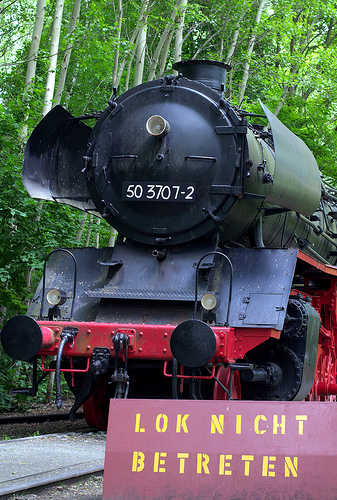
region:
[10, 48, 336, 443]
Black and red train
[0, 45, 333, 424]
Train on the tracks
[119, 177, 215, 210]
50 3707-2 on the front of the train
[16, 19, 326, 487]
Photo taken during the day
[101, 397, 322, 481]
Yellow lettering on a red sign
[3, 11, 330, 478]
No people shown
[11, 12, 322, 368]
Trees behind the train.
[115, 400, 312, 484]
"Lok Nicht Betreten" on a sign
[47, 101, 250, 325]
Three lights on the train.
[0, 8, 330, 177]
Green leaves on the trees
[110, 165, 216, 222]
numbers are on train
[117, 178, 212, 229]
the numbers are white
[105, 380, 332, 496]
the sign is red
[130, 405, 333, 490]
letters are on the sign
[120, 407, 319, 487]
the letters are yellow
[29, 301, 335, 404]
base of train is red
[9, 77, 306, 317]
the train is black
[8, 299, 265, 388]
round objects on front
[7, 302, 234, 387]
round objects are black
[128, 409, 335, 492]
words in a foreign language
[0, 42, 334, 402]
an old train engine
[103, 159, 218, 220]
train has a number 50 3707-2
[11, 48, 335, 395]
train engine is green, black and red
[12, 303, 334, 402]
lower part of the train is red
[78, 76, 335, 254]
upper part of the train is green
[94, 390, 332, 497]
a purple sign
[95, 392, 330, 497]
a rectangular sign is purple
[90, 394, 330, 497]
sign has yellow letters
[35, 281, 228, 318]
headlights are small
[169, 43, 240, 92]
tube on top is black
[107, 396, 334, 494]
red do not enter sign in German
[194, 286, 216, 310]
train engine left headlight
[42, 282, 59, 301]
train engine right headlight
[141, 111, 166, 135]
train engine top headlight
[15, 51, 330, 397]
a steam train engine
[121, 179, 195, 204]
train engine handwritten number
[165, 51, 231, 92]
train engine smoke stack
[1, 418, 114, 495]
a set of train tracks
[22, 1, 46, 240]
a tall white tree trunk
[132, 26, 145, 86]
a tall white tree trunk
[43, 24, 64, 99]
the trunk of a tree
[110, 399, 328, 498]
a sign with yellow letters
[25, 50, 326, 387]
the engine of a trian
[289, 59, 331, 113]
the leaves of trees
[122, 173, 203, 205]
white numbers on a train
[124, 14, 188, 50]
the trunks of trees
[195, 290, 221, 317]
a light on a train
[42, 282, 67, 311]
a light on a train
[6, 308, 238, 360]
a red bumper on a train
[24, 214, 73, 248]
leaves of a tree